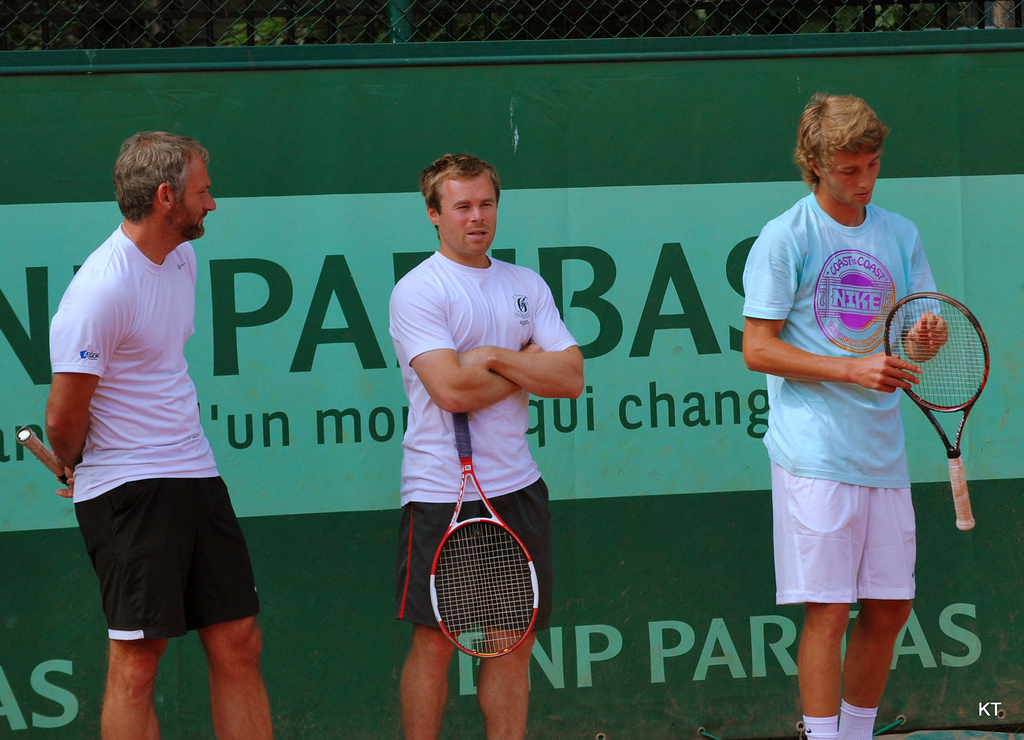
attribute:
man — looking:
[385, 156, 583, 739]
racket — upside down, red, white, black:
[426, 414, 540, 657]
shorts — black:
[75, 479, 259, 645]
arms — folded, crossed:
[400, 303, 582, 409]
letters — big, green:
[207, 256, 383, 379]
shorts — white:
[768, 454, 915, 605]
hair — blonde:
[796, 93, 886, 193]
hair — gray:
[113, 131, 205, 221]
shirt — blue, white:
[743, 191, 939, 498]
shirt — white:
[383, 252, 575, 505]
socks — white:
[796, 712, 839, 739]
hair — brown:
[424, 152, 498, 219]